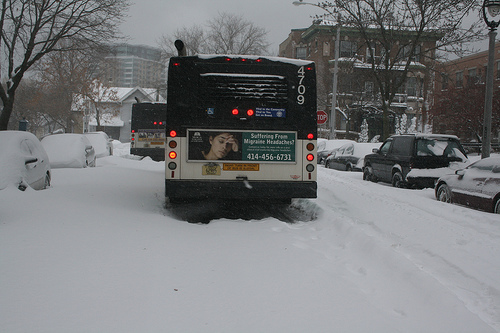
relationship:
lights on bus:
[229, 100, 256, 120] [159, 35, 321, 215]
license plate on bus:
[221, 161, 260, 170] [163, 38, 318, 206]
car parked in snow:
[39, 130, 97, 169] [44, 133, 129, 205]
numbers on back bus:
[294, 65, 308, 107] [159, 35, 321, 215]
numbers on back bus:
[246, 151, 296, 161] [159, 35, 321, 215]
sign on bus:
[253, 105, 288, 122] [158, 49, 326, 218]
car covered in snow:
[35, 131, 97, 169] [71, 133, 78, 143]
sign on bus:
[186, 125, 299, 170] [159, 35, 321, 215]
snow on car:
[414, 141, 469, 182] [361, 120, 473, 202]